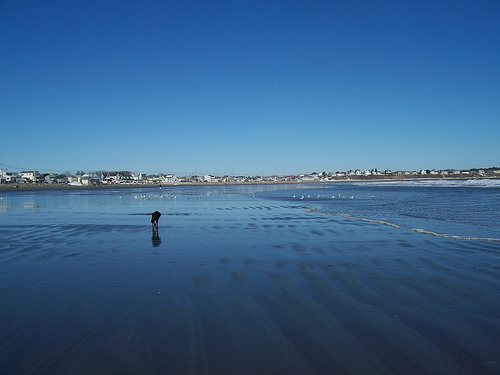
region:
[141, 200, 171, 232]
man stands on frozen lake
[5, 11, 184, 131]
sky is crystal blue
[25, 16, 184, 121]
no clouds are in sky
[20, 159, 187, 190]
many white buildings in background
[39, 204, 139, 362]
lake is frozen over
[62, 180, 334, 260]
dark blue patches on icy water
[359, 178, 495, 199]
white wave in distance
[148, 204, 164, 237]
person is bending over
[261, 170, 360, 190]
snow on shore near buildings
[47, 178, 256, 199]
sun reflects on icy lake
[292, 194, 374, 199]
group of birds swimming far off shore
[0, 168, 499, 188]
coast land with houses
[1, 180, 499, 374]
dark blue ocean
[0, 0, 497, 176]
clear beautiful blue sky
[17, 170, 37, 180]
one house in long row of houses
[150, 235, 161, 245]
shadow in the water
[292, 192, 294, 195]
bird on the water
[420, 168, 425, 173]
house on the beach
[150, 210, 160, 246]
black object and it's shadow standing in shallow water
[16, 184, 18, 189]
person standing on beach in the distance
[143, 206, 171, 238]
animal in the water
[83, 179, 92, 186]
house around the reservior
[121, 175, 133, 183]
house around the reservior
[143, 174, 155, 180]
house around the reservior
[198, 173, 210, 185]
house around the reservior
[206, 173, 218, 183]
house around the reservior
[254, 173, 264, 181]
house around the reservior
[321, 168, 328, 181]
house around the reservior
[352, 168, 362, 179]
house around the reservior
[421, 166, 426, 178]
house around the reservior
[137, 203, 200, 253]
a person picking something up off the wet sand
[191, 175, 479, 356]
a blue shoreline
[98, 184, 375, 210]
seagulls flocked together at the shore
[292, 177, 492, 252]
waves of the ocean hitting the shoreline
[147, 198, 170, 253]
a person casting a shadow on the sand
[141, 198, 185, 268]
a person walking along the shore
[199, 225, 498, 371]
wet sand at a beach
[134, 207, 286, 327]
a person walking along the beach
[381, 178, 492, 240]
waves hitting the beach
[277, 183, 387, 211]
a flock of seagulls at the beach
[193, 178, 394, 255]
the water is shallow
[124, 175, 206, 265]
a dog on the sand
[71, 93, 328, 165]
the sky is clear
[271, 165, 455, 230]
birds on the water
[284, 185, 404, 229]
birds on the water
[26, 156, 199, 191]
houses in the distance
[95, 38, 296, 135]
the sky is clear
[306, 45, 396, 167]
the sky is clear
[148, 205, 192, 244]
the dog is black